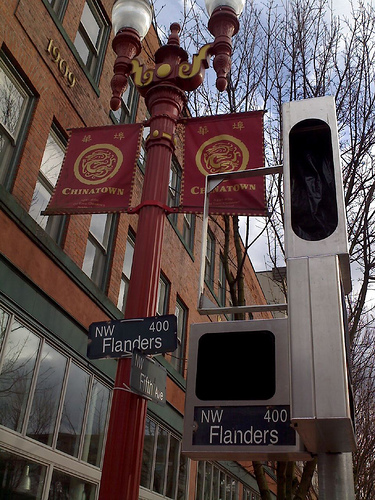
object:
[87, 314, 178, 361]
street sign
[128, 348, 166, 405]
street sign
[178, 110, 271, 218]
flag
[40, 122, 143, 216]
flag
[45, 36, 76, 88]
numbers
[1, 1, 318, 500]
building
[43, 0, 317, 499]
wood trim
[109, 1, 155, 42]
glass lamp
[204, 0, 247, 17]
glass lamp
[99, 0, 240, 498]
pole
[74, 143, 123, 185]
golden dragon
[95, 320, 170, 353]
lettering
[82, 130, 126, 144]
chinese characters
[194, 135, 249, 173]
golden dragon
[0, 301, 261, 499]
row of windows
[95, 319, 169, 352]
nw 400 flanders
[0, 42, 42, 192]
windows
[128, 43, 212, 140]
gold details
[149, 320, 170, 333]
400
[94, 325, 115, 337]
nw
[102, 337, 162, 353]
flanders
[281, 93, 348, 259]
silver object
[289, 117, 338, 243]
black center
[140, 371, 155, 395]
fifth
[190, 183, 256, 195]
chinatown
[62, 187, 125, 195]
chinatown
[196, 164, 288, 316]
sign holder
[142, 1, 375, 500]
trees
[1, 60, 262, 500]
reflection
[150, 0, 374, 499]
sky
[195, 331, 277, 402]
cross walk signal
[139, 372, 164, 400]
fifth ave